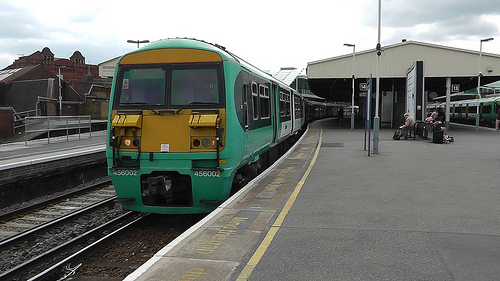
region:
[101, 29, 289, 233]
the train is green and yellow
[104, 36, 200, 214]
the train is green and yellow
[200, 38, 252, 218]
the train is green and yellow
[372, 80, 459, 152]
people sitting on the bench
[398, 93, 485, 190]
people sitting on the bench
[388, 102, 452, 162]
people sitting on the bench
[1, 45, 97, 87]
part of red buildings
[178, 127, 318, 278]
yellow letters on cement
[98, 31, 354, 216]
aqua and yellow train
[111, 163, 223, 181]
white letters on train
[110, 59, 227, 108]
front windows of train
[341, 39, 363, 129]
tall white street light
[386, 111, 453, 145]
people sitting on black bench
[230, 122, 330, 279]
long yellow painted line on cement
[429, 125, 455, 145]
belongings of waiting person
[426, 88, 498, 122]
green and white train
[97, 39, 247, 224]
A yellow and green train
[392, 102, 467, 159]
People waiting for a train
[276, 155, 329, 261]
A yellow stripe painted on the sidewalk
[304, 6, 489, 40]
A gray cloudy day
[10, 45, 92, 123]
Red brick buildings in the distance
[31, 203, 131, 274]
Two sets of train tracks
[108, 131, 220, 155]
Head lights on the front of the train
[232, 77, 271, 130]
Dark green around the windows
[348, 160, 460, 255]
The cement is gray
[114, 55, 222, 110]
Windshield of the train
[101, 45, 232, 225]
the front of a train.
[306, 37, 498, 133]
a small structure.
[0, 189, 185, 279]
train tracks under a train.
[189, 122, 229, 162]
a head light.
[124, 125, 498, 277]
a loading platform on a train.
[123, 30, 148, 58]
a parking lot light.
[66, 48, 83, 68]
a tree with leaves.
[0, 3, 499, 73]
a cloud filled sky.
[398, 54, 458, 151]
a pile of clutter.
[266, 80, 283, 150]
a door on the side of a train car.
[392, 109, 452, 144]
people sitting down on benches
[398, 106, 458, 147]
people waiting for train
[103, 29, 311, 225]
green and yellow train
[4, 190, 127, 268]
part of the train tracks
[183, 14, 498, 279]
train station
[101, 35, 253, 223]
front of the train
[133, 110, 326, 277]
warning area of train station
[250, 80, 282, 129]
side windows of train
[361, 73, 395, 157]
information posts on train station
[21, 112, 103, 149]
safety rail at train station